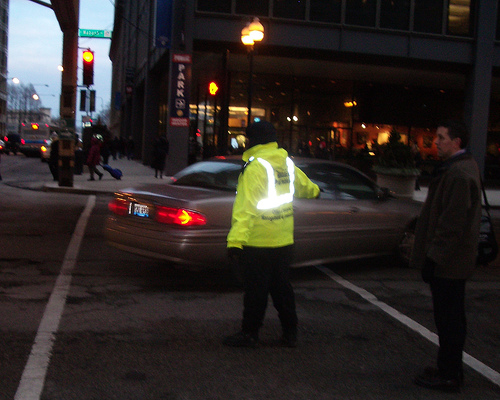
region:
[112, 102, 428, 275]
car driving thru the intersection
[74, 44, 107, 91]
traffic light on red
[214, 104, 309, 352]
man crossing the streeet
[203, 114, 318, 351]
man wearing bright yellow jacket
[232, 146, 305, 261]
yellow jacket with reflectors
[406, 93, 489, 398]
man wearing brown coat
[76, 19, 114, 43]
street sign above traffic light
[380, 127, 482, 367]
man carrying black bag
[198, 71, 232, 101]
walk signal on the hand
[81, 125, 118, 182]
woman rolling a blue suitcase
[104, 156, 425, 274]
a car on a street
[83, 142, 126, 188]
a paerson pulling a suite case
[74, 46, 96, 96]
a stop light on a pole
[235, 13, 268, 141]
a street light on a pole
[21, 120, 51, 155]
a bus on a street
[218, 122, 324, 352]
a man flaging traffic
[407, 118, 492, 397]
a man standing on a street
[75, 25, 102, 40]
a green white sign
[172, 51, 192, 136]
a sign on a building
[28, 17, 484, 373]
The traffic is moving through a city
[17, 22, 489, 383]
Some people are in the crosswalk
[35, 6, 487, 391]
Some people are doing some shopping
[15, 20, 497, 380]
A person is directing the traffic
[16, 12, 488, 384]
A person is wearing a reflector coat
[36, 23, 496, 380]
A car is making a right turn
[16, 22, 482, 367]
A traffic light is operating in a city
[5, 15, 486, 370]
The traffic is obeying the law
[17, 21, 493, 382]
The people are having a great time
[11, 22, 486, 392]
The people are enjoying their day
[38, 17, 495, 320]
a police directing traffic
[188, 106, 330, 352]
the policeman is wearing a yellow coat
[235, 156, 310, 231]
his coat is flourescent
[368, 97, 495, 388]
a man standing by the curb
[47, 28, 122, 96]
a traffic light in the area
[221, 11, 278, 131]
a street light in the area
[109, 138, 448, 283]
a car on the street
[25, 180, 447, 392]
a crosswalk for pedestrians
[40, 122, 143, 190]
people in the background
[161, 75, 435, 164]
a business near the street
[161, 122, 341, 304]
man in yellow outfit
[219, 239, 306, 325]
dark pants on man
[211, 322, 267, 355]
foot of the man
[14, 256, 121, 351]
white line on street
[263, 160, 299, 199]
black words on back of shirt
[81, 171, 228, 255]
red lights on back of car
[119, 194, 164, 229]
license plate on back of car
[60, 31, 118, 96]
light in the photo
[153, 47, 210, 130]
words on a pole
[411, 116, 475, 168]
head of a man